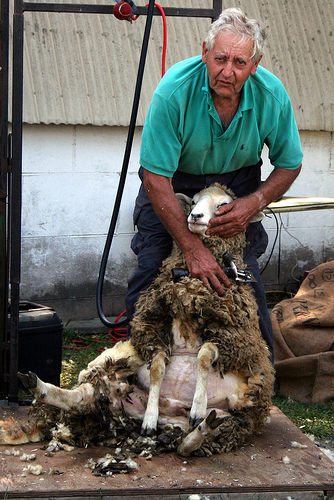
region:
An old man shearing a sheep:
[55, 69, 326, 453]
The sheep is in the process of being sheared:
[64, 180, 291, 455]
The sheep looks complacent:
[175, 187, 250, 232]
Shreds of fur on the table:
[31, 425, 206, 484]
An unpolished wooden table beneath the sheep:
[35, 439, 331, 495]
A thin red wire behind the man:
[62, 315, 135, 356]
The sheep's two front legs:
[130, 321, 233, 420]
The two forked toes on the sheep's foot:
[197, 406, 228, 435]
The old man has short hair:
[207, 14, 276, 56]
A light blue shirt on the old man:
[151, 54, 295, 183]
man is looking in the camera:
[141, 1, 306, 164]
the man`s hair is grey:
[190, 0, 266, 66]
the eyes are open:
[191, 44, 245, 68]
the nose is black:
[185, 208, 205, 219]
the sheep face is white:
[163, 175, 253, 235]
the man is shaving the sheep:
[115, 153, 297, 309]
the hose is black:
[52, 18, 169, 329]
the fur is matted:
[115, 211, 287, 427]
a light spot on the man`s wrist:
[240, 183, 276, 225]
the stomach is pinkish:
[128, 331, 239, 404]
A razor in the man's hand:
[172, 258, 255, 283]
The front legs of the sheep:
[148, 346, 220, 427]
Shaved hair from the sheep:
[6, 428, 138, 478]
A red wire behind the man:
[148, 3, 176, 74]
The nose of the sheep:
[190, 212, 202, 218]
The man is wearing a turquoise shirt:
[142, 59, 306, 169]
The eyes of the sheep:
[193, 197, 228, 208]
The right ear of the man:
[202, 42, 207, 62]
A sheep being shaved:
[20, 185, 272, 440]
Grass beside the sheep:
[277, 394, 333, 432]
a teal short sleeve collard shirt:
[139, 55, 306, 170]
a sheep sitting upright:
[18, 182, 276, 458]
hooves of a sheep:
[14, 366, 227, 437]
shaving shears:
[174, 253, 257, 288]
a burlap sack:
[269, 261, 333, 400]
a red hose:
[107, 0, 168, 342]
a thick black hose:
[96, 1, 140, 324]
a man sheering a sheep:
[17, 6, 303, 454]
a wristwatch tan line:
[250, 189, 268, 211]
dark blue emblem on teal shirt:
[238, 142, 246, 151]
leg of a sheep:
[179, 336, 224, 432]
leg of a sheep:
[132, 342, 175, 438]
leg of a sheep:
[9, 349, 108, 423]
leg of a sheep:
[157, 395, 240, 463]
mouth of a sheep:
[184, 219, 209, 229]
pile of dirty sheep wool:
[82, 446, 140, 479]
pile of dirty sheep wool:
[42, 415, 78, 456]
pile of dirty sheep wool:
[22, 459, 42, 479]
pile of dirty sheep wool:
[13, 448, 37, 463]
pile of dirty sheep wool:
[1, 443, 19, 457]